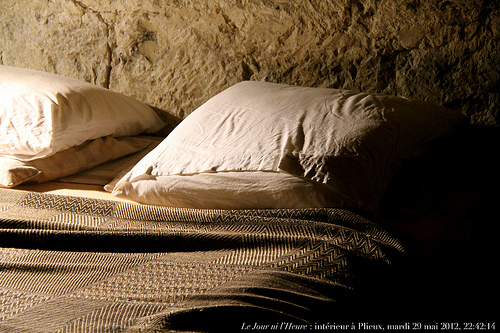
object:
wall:
[2, 6, 497, 249]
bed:
[9, 144, 427, 331]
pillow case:
[0, 62, 166, 161]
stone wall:
[2, 2, 494, 172]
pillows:
[2, 65, 161, 147]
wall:
[3, 2, 498, 108]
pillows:
[1, 65, 429, 209]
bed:
[1, 57, 451, 332]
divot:
[343, 5, 380, 46]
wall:
[104, 12, 297, 96]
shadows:
[385, 188, 497, 272]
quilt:
[65, 204, 437, 314]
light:
[0, 83, 56, 156]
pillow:
[0, 62, 167, 187]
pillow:
[101, 80, 436, 210]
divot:
[432, 60, 453, 92]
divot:
[86, 148, 413, 321]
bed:
[74, 131, 348, 308]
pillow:
[100, 95, 412, 216]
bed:
[47, 161, 292, 309]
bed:
[4, 109, 469, 329]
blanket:
[0, 190, 410, 330]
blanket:
[0, 138, 405, 331]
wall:
[3, 5, 495, 179]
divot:
[375, 44, 403, 88]